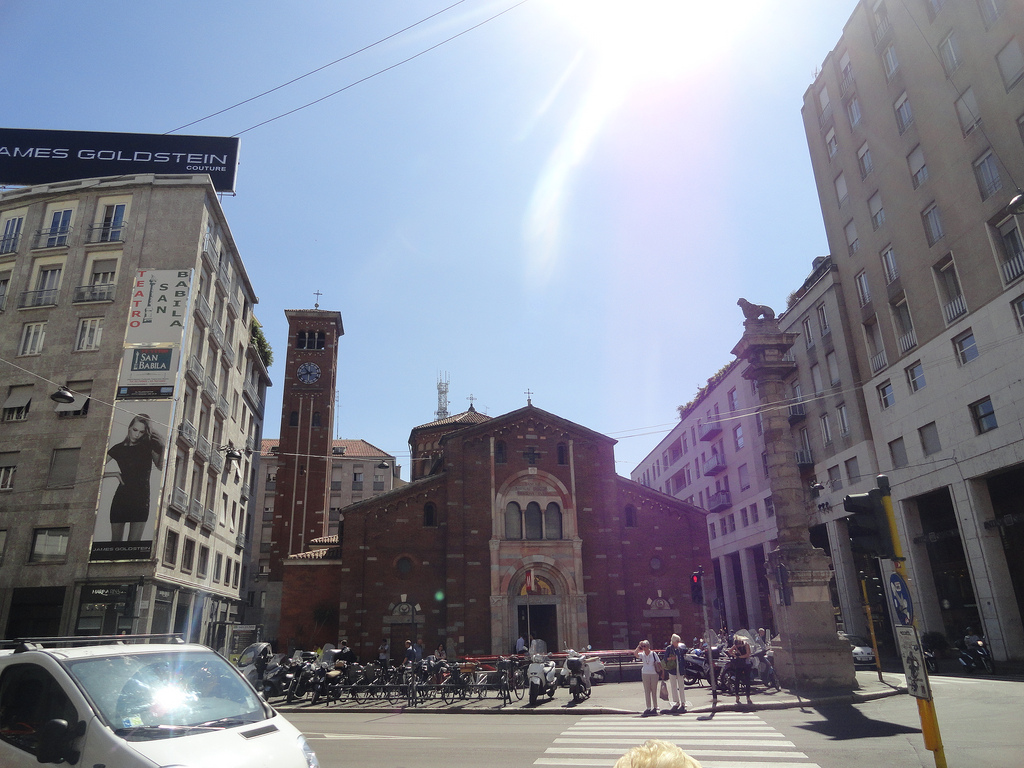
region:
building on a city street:
[327, 375, 738, 707]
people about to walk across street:
[620, 625, 761, 719]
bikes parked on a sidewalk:
[309, 662, 512, 709]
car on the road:
[4, 611, 316, 766]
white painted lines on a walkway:
[547, 725, 796, 754]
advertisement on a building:
[104, 322, 181, 566]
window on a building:
[918, 252, 980, 330]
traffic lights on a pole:
[834, 463, 906, 595]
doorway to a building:
[510, 597, 572, 661]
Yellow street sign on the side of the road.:
[848, 478, 970, 764]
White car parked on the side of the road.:
[8, 610, 303, 765]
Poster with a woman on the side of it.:
[108, 262, 172, 545]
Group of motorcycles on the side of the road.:
[239, 598, 613, 715]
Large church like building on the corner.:
[313, 364, 798, 694]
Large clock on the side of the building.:
[277, 356, 329, 391]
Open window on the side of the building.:
[40, 356, 101, 434]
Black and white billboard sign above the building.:
[11, 110, 245, 203]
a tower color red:
[262, 282, 355, 562]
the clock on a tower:
[284, 351, 327, 397]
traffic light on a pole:
[831, 462, 918, 583]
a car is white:
[4, 615, 324, 764]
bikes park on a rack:
[273, 638, 602, 714]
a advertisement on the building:
[5, 110, 287, 351]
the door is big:
[510, 581, 567, 659]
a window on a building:
[866, 380, 898, 409]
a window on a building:
[897, 367, 935, 387]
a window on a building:
[950, 308, 992, 373]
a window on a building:
[957, 399, 1005, 431]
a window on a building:
[905, 421, 945, 448]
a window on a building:
[809, 469, 847, 493]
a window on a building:
[758, 502, 779, 512]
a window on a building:
[736, 506, 765, 522]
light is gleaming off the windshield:
[134, 670, 229, 734]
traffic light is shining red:
[681, 556, 719, 617]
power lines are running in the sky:
[134, 1, 496, 175]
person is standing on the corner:
[618, 633, 675, 726]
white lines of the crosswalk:
[530, 690, 819, 766]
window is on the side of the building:
[868, 374, 907, 413]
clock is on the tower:
[296, 352, 322, 394]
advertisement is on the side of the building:
[77, 250, 199, 555]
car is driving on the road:
[2, 630, 328, 761]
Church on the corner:
[281, 375, 771, 685]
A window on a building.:
[964, 392, 1003, 437]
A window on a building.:
[546, 501, 570, 533]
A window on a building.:
[498, 494, 522, 542]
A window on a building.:
[87, 256, 113, 289]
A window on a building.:
[94, 198, 132, 241]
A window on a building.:
[41, 201, 67, 243]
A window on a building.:
[915, 416, 942, 446]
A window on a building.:
[896, 362, 928, 388]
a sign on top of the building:
[0, 126, 239, 197]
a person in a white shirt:
[638, 647, 664, 714]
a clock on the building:
[294, 367, 324, 386]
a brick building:
[307, 401, 741, 674]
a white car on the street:
[2, 638, 317, 759]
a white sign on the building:
[89, 271, 181, 548]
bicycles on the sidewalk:
[310, 663, 538, 698]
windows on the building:
[502, 505, 573, 543]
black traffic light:
[834, 470, 904, 570]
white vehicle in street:
[3, 614, 323, 767]